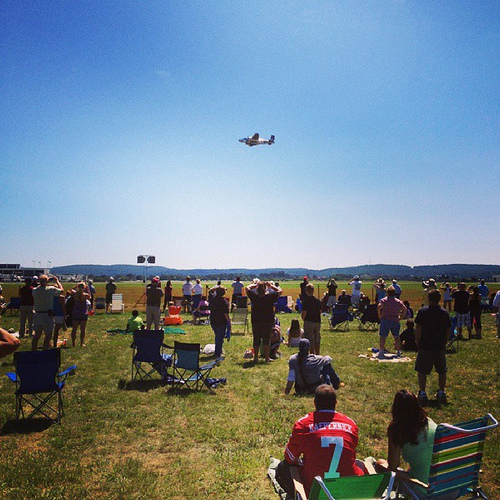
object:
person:
[412, 287, 451, 402]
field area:
[0, 281, 500, 500]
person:
[208, 286, 231, 359]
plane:
[238, 132, 276, 147]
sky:
[0, 0, 500, 271]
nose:
[238, 138, 247, 144]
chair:
[5, 346, 78, 426]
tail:
[270, 135, 274, 142]